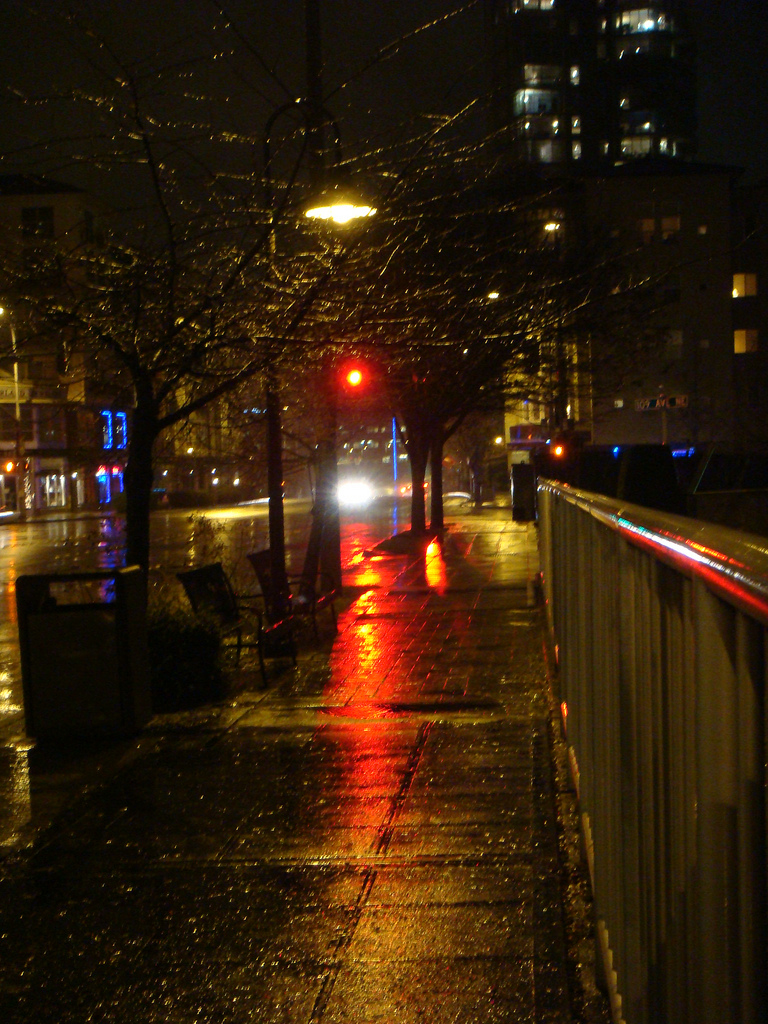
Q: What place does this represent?
A: It represents the sidewalk.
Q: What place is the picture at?
A: It is at the sidewalk.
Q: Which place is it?
A: It is a sidewalk.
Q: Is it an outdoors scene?
A: Yes, it is outdoors.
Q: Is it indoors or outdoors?
A: It is outdoors.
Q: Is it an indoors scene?
A: No, it is outdoors.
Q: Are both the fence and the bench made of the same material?
A: Yes, both the fence and the bench are made of wood.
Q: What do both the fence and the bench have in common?
A: The material, both the fence and the bench are wooden.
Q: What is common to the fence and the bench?
A: The material, both the fence and the bench are wooden.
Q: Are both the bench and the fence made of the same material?
A: Yes, both the bench and the fence are made of wood.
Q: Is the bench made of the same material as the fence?
A: Yes, both the bench and the fence are made of wood.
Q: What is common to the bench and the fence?
A: The material, both the bench and the fence are wooden.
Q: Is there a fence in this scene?
A: Yes, there is a fence.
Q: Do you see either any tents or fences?
A: Yes, there is a fence.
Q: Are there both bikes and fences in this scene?
A: No, there is a fence but no bikes.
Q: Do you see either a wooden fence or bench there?
A: Yes, there is a wood fence.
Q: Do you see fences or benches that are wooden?
A: Yes, the fence is wooden.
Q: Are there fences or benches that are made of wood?
A: Yes, the fence is made of wood.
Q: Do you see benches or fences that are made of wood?
A: Yes, the fence is made of wood.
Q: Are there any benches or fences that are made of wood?
A: Yes, the fence is made of wood.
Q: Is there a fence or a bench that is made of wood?
A: Yes, the fence is made of wood.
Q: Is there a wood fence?
A: Yes, there is a fence that is made of wood.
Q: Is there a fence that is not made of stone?
A: Yes, there is a fence that is made of wood.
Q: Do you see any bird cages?
A: No, there are no bird cages.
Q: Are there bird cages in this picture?
A: No, there are no bird cages.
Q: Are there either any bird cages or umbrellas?
A: No, there are no bird cages or umbrellas.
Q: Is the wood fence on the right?
A: Yes, the fence is on the right of the image.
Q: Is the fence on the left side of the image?
A: No, the fence is on the right of the image.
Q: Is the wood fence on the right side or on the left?
A: The fence is on the right of the image.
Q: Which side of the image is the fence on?
A: The fence is on the right of the image.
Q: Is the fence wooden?
A: Yes, the fence is wooden.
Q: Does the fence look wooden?
A: Yes, the fence is wooden.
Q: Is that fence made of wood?
A: Yes, the fence is made of wood.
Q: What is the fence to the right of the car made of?
A: The fence is made of wood.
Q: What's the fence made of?
A: The fence is made of wood.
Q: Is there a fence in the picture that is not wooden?
A: No, there is a fence but it is wooden.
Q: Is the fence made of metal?
A: No, the fence is made of wood.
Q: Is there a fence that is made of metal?
A: No, there is a fence but it is made of wood.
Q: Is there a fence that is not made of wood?
A: No, there is a fence but it is made of wood.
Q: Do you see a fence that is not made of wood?
A: No, there is a fence but it is made of wood.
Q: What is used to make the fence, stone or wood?
A: The fence is made of wood.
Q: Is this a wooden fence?
A: Yes, this is a wooden fence.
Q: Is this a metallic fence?
A: No, this is a wooden fence.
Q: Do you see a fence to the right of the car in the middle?
A: Yes, there is a fence to the right of the car.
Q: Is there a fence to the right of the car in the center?
A: Yes, there is a fence to the right of the car.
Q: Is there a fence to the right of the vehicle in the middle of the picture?
A: Yes, there is a fence to the right of the car.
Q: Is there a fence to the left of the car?
A: No, the fence is to the right of the car.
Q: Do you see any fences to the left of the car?
A: No, the fence is to the right of the car.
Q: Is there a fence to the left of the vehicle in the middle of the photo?
A: No, the fence is to the right of the car.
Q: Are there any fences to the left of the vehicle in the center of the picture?
A: No, the fence is to the right of the car.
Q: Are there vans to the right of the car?
A: No, there is a fence to the right of the car.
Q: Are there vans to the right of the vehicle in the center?
A: No, there is a fence to the right of the car.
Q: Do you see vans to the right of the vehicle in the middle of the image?
A: No, there is a fence to the right of the car.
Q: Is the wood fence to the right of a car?
A: Yes, the fence is to the right of a car.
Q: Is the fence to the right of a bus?
A: No, the fence is to the right of a car.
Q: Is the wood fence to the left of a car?
A: No, the fence is to the right of a car.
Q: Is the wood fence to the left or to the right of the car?
A: The fence is to the right of the car.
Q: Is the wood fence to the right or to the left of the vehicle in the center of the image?
A: The fence is to the right of the car.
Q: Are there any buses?
A: No, there are no buses.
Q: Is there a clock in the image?
A: No, there are no clocks.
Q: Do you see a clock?
A: No, there are no clocks.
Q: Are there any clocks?
A: No, there are no clocks.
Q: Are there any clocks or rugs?
A: No, there are no clocks or rugs.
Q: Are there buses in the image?
A: No, there are no buses.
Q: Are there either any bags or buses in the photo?
A: No, there are no buses or bags.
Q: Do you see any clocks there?
A: No, there are no clocks.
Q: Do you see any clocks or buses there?
A: No, there are no clocks or buses.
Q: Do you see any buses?
A: No, there are no buses.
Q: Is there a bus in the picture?
A: No, there are no buses.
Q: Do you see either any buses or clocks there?
A: No, there are no buses or clocks.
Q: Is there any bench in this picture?
A: Yes, there is a bench.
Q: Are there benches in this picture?
A: Yes, there is a bench.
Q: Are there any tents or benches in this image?
A: Yes, there is a bench.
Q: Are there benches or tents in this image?
A: Yes, there is a bench.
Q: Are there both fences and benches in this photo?
A: Yes, there are both a bench and a fence.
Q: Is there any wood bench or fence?
A: Yes, there is a wood bench.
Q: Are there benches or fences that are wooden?
A: Yes, the bench is wooden.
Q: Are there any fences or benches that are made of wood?
A: Yes, the bench is made of wood.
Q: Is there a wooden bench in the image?
A: Yes, there is a wood bench.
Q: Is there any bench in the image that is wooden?
A: Yes, there is a bench that is wooden.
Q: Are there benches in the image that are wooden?
A: Yes, there is a bench that is wooden.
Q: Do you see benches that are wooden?
A: Yes, there is a bench that is wooden.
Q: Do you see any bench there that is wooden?
A: Yes, there is a bench that is wooden.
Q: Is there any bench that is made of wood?
A: Yes, there is a bench that is made of wood.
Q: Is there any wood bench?
A: Yes, there is a bench that is made of wood.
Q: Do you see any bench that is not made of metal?
A: Yes, there is a bench that is made of wood.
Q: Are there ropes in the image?
A: No, there are no ropes.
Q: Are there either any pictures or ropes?
A: No, there are no ropes or pictures.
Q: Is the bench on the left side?
A: Yes, the bench is on the left of the image.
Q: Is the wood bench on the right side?
A: No, the bench is on the left of the image.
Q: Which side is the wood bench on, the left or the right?
A: The bench is on the left of the image.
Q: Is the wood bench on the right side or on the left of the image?
A: The bench is on the left of the image.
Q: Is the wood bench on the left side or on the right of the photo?
A: The bench is on the left of the image.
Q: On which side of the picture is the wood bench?
A: The bench is on the left of the image.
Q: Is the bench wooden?
A: Yes, the bench is wooden.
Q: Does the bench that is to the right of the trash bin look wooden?
A: Yes, the bench is wooden.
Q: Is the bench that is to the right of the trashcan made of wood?
A: Yes, the bench is made of wood.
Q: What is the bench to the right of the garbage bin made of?
A: The bench is made of wood.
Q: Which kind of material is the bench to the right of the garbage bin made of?
A: The bench is made of wood.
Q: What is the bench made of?
A: The bench is made of wood.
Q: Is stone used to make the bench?
A: No, the bench is made of wood.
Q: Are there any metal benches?
A: No, there is a bench but it is made of wood.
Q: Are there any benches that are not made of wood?
A: No, there is a bench but it is made of wood.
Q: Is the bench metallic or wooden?
A: The bench is wooden.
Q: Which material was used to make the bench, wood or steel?
A: The bench is made of wood.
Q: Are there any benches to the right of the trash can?
A: Yes, there is a bench to the right of the trash can.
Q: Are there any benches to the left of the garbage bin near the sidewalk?
A: No, the bench is to the right of the garbage bin.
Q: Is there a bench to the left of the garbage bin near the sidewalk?
A: No, the bench is to the right of the garbage bin.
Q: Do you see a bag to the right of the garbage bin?
A: No, there is a bench to the right of the garbage bin.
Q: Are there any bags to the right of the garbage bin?
A: No, there is a bench to the right of the garbage bin.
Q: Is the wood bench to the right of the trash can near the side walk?
A: Yes, the bench is to the right of the trashcan.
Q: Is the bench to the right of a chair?
A: No, the bench is to the right of the trashcan.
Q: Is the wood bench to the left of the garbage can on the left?
A: No, the bench is to the right of the trash can.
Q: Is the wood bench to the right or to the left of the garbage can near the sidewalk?
A: The bench is to the right of the trash can.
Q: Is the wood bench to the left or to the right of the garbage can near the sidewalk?
A: The bench is to the right of the trash can.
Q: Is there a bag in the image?
A: No, there are no bags.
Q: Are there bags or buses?
A: No, there are no bags or buses.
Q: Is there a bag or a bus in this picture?
A: No, there are no bags or buses.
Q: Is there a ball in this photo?
A: No, there are no balls.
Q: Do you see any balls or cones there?
A: No, there are no balls or cones.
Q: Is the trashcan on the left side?
A: Yes, the trashcan is on the left of the image.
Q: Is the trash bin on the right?
A: No, the trash bin is on the left of the image.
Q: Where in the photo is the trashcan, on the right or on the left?
A: The trashcan is on the left of the image.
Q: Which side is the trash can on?
A: The trash can is on the left of the image.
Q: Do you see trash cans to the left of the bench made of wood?
A: Yes, there is a trash can to the left of the bench.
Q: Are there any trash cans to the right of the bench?
A: No, the trash can is to the left of the bench.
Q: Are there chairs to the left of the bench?
A: No, there is a trash can to the left of the bench.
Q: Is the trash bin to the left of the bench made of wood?
A: Yes, the trash bin is to the left of the bench.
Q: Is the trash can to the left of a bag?
A: No, the trash can is to the left of the bench.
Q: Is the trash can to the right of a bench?
A: No, the trash can is to the left of a bench.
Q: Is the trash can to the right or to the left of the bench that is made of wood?
A: The trash can is to the left of the bench.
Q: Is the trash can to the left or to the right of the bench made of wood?
A: The trash can is to the left of the bench.